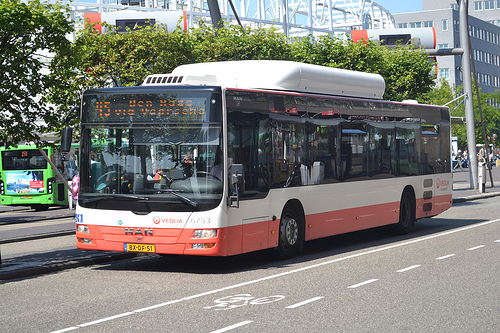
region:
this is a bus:
[125, 58, 450, 209]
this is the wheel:
[285, 201, 304, 248]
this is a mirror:
[223, 165, 255, 210]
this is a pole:
[451, 15, 498, 154]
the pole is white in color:
[465, 27, 475, 67]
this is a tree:
[8, 15, 85, 90]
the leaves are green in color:
[49, 24, 89, 78]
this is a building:
[416, 7, 467, 39]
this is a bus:
[85, 67, 430, 262]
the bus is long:
[77, 75, 429, 262]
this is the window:
[236, 123, 273, 203]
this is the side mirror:
[228, 161, 248, 201]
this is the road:
[352, 250, 441, 323]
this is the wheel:
[281, 206, 305, 249]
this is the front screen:
[106, 100, 211, 177]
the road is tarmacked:
[331, 240, 446, 331]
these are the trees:
[115, 23, 165, 60]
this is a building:
[480, 22, 498, 49]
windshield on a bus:
[78, 120, 218, 202]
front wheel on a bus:
[277, 204, 304, 255]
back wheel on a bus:
[396, 191, 416, 235]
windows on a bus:
[228, 114, 451, 184]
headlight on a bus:
[193, 227, 215, 240]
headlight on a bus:
[75, 223, 91, 232]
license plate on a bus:
[122, 241, 156, 253]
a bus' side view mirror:
[230, 161, 245, 208]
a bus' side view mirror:
[58, 124, 75, 151]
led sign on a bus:
[82, 93, 214, 122]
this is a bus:
[70, 67, 435, 257]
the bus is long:
[86, 63, 453, 258]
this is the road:
[384, 237, 458, 317]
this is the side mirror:
[44, 122, 77, 164]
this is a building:
[480, 17, 492, 56]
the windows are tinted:
[330, 110, 398, 165]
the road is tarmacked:
[351, 251, 461, 328]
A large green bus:
[0, 137, 116, 212]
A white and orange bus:
[64, 58, 454, 265]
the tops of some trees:
[5, 3, 437, 193]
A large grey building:
[394, 5, 499, 114]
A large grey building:
[421, 0, 498, 24]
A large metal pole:
[388, 0, 478, 188]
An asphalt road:
[0, 169, 499, 331]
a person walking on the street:
[452, 147, 467, 169]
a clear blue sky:
[25, 0, 422, 41]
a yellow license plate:
[126, 240, 156, 254]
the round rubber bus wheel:
[277, 214, 303, 252]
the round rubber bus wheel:
[400, 192, 417, 232]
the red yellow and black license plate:
[122, 243, 154, 252]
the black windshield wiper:
[138, 185, 198, 210]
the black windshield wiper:
[81, 191, 148, 205]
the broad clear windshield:
[82, 126, 219, 208]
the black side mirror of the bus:
[230, 163, 243, 192]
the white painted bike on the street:
[205, 290, 286, 312]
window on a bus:
[80, 90, 220, 208]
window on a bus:
[230, 91, 291, 186]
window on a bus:
[280, 115, 330, 185]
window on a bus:
[340, 115, 370, 185]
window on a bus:
[420, 115, 450, 180]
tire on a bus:
[391, 181, 416, 231]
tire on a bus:
[270, 192, 311, 253]